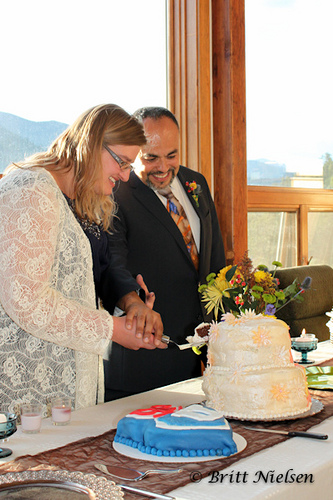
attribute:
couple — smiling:
[2, 104, 222, 414]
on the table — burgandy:
[2, 341, 333, 499]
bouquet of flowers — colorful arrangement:
[196, 257, 311, 326]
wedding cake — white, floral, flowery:
[203, 314, 311, 419]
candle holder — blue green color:
[292, 337, 317, 361]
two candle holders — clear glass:
[21, 405, 42, 435]